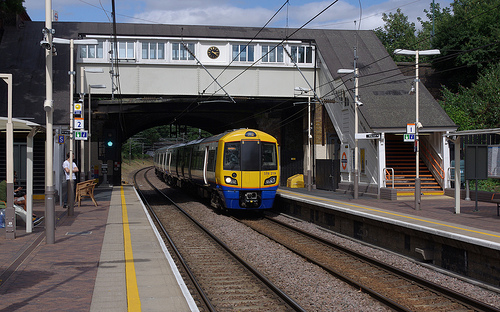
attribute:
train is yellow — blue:
[154, 125, 279, 211]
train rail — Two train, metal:
[241, 216, 496, 310]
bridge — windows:
[54, 19, 317, 100]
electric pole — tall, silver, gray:
[413, 50, 424, 216]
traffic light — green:
[107, 140, 114, 147]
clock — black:
[207, 46, 220, 59]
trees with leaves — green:
[380, 0, 499, 129]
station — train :
[36, 26, 484, 297]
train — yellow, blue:
[152, 115, 290, 215]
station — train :
[18, 8, 478, 310]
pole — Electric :
[324, 44, 438, 217]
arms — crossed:
[62, 160, 78, 180]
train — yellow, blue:
[144, 120, 285, 218]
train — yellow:
[150, 125, 280, 215]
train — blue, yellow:
[146, 129, 286, 221]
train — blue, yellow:
[155, 126, 300, 222]